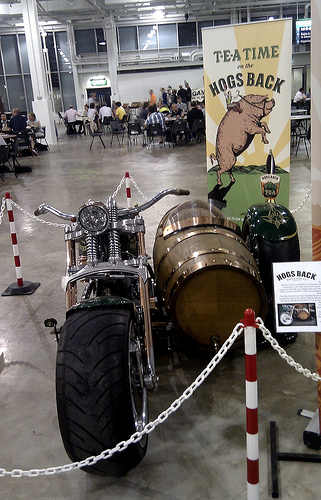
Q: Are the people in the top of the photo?
A: Yes, the people are in the top of the image.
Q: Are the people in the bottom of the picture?
A: No, the people are in the top of the image.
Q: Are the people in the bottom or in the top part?
A: The people are in the top of the image.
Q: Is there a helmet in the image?
A: No, there are no helmets.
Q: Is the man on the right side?
A: Yes, the man is on the right of the image.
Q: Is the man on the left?
A: No, the man is on the right of the image.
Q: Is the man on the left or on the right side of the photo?
A: The man is on the right of the image.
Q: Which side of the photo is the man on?
A: The man is on the right of the image.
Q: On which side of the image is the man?
A: The man is on the right of the image.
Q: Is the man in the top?
A: Yes, the man is in the top of the image.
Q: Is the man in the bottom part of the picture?
A: No, the man is in the top of the image.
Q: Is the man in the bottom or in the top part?
A: The man is in the top of the image.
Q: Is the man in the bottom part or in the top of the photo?
A: The man is in the top of the image.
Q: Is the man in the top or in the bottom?
A: The man is in the top of the image.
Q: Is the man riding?
A: Yes, the man is riding.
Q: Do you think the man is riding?
A: Yes, the man is riding.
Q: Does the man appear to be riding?
A: Yes, the man is riding.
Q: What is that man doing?
A: The man is riding.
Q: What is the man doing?
A: The man is riding.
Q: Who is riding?
A: The man is riding.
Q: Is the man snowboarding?
A: No, the man is riding.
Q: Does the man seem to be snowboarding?
A: No, the man is riding.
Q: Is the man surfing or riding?
A: The man is riding.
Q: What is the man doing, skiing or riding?
A: The man is riding.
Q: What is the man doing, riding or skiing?
A: The man is riding.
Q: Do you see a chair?
A: Yes, there is a chair.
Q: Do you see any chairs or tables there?
A: Yes, there is a chair.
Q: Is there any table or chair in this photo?
A: Yes, there is a chair.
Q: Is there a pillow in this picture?
A: No, there are no pillows.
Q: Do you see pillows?
A: No, there are no pillows.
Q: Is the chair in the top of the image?
A: Yes, the chair is in the top of the image.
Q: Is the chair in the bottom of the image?
A: No, the chair is in the top of the image.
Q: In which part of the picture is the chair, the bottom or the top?
A: The chair is in the top of the image.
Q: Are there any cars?
A: No, there are no cars.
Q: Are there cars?
A: No, there are no cars.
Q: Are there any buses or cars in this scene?
A: No, there are no cars or buses.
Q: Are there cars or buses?
A: No, there are no cars or buses.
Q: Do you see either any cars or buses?
A: No, there are no cars or buses.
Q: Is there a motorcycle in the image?
A: Yes, there is a motorcycle.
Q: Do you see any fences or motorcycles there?
A: Yes, there is a motorcycle.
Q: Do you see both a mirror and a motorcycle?
A: No, there is a motorcycle but no mirrors.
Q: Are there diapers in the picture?
A: No, there are no diapers.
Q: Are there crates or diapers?
A: No, there are no diapers or crates.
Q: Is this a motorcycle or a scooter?
A: This is a motorcycle.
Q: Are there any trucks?
A: No, there are no trucks.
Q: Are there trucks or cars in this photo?
A: No, there are no trucks or cars.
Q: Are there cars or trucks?
A: No, there are no trucks or cars.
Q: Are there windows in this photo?
A: Yes, there are windows.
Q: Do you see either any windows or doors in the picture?
A: Yes, there are windows.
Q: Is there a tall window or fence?
A: Yes, there are tall windows.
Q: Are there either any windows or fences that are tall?
A: Yes, the windows are tall.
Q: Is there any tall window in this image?
A: Yes, there are tall windows.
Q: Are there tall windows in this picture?
A: Yes, there are tall windows.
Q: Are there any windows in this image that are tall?
A: Yes, there are windows that are tall.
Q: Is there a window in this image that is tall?
A: Yes, there are windows that are tall.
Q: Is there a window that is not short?
A: Yes, there are tall windows.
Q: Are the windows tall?
A: Yes, the windows are tall.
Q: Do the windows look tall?
A: Yes, the windows are tall.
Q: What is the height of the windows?
A: The windows are tall.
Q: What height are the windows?
A: The windows are tall.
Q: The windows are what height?
A: The windows are tall.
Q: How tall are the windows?
A: The windows are tall.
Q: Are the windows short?
A: No, the windows are tall.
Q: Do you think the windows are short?
A: No, the windows are tall.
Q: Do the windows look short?
A: No, the windows are tall.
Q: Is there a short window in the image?
A: No, there are windows but they are tall.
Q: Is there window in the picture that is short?
A: No, there are windows but they are tall.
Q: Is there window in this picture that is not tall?
A: No, there are windows but they are tall.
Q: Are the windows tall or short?
A: The windows are tall.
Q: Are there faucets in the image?
A: No, there are no faucets.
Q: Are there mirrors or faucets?
A: No, there are no faucets or mirrors.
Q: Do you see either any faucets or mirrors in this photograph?
A: No, there are no faucets or mirrors.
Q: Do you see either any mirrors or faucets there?
A: No, there are no faucets or mirrors.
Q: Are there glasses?
A: No, there are no glasses.